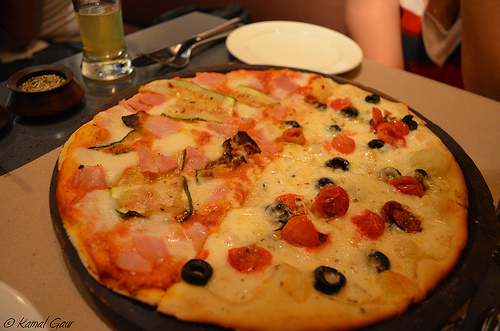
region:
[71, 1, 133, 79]
a glass of juice on a table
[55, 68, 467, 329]
a pizza on a black plate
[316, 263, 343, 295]
a slice of black olive on a pizza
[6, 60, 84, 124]
a wooden pot on a table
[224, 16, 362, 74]
a white plate on a table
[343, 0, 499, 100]
a person sitting at a table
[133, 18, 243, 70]
utensils on a table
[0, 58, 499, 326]
a brown paper mat on a table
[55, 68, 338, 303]
a half pizza with zucchini and ham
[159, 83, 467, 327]
a half pizza with black olives and dry tomatoes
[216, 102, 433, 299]
this side has pepperoni and olives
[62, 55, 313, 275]
this side has peppers and bacon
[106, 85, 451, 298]
pizza on a black platter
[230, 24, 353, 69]
the plate is white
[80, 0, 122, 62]
green liquid in glass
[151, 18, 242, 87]
the utensils are silver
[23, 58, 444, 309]
the pizza has been cooked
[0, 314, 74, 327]
the text is black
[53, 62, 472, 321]
This is a pizza.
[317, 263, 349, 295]
Here is a black olive.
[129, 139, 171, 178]
This is a piece of ham.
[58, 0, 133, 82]
The beer is yellow.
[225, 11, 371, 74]
The plate is white.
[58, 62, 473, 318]
The pizza looks tasty.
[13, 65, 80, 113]
Here is some pepper.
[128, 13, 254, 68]
The knife and fork are silver.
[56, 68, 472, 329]
pizza with different topping on both halves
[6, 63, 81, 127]
small bowl with spices in it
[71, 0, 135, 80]
glass with beer inside it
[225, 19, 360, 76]
small round white plate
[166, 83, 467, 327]
half of a pizza with pepperoni and black olives on it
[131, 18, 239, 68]
silver fork and knife on table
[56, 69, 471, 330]
pizza with topping on it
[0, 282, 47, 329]
part of a small white plate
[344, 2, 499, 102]
person sitting at table ready to eat pizza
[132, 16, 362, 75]
fork, knife, and plate ready to be used for pizza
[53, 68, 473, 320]
The pizza looks crispy.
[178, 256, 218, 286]
The olives are black.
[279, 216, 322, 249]
The tomatoes are red.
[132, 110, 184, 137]
The ham is pink.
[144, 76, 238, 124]
The zucchini is green.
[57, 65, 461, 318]
The cheese is white.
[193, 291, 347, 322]
The crust is crispy.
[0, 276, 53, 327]
The plate is white.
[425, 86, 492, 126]
The table is brown.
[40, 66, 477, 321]
The pizza is on the table.